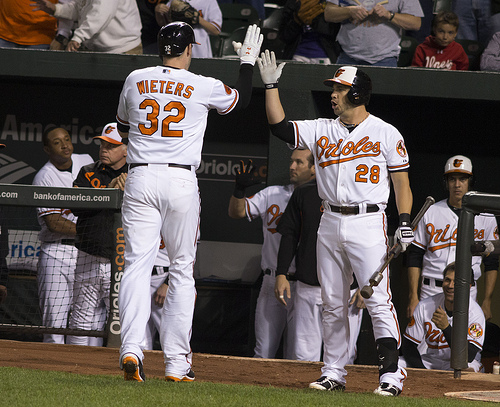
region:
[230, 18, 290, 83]
two hands with gloves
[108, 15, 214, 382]
baseball player in white uniform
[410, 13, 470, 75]
boy wearing red sweatshirt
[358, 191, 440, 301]
baseball bat with weight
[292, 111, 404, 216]
orange and white baseball jersey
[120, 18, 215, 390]
back of a baseball player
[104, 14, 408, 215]
two baseball players high fiving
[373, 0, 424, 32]
man's forearm and wristwatch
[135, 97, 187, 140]
number thirty two in orange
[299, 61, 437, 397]
weighted bat in baseball player's hand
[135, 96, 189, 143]
The number 32 on back of a uniform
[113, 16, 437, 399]
Two baseball players playing baseball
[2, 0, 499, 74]
Spectators watching the game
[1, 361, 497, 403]
Green grass on the field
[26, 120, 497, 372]
Players in the dugout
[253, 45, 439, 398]
A player holding a bat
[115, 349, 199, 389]
A pair of sneakers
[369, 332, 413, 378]
A black leg guard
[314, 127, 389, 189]
Orange writing on white uniform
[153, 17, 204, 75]
Black helmet on player's head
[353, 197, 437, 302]
A black bat in the player's hand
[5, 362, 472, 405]
Grass by the dugout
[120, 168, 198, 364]
This player has white pants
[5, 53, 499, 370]
The dugout for the Orioles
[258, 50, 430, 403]
An Orioles player holding the bat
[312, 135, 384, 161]
The Orioles logo on the shirt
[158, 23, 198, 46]
The helmet is black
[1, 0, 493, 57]
The spectators above the dugout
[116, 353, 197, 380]
The player has black and orange shoes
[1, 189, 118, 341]
A fence in front of the dugout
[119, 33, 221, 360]
this is a man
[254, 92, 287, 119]
the man is light skinned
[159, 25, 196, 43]
this is a helmet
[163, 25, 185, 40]
the helmet is black in color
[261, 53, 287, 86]
this is a glove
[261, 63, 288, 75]
the glove is white in color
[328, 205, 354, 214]
this is a belt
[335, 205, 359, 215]
the belt is black in color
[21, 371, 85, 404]
this is a grass area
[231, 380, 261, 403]
the grass is green in color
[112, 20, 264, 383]
A baseball player with his hand up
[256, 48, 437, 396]
A baseball player with his hand up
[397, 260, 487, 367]
A baseball player sitting down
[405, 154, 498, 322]
A baseball player wearing a helmet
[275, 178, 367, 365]
A man in a black shirt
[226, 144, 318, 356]
A baseball player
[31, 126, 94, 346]
A baseball player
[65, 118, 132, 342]
A man in a black jacket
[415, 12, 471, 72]
A child in a red jacket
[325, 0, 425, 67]
A person in a grey shirt